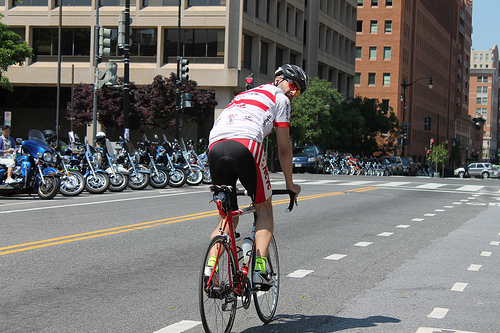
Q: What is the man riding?
A: A bicycle.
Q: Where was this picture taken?
A: On a road.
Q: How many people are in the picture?
A: 1.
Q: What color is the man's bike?
A: Red.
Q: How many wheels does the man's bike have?
A: 2.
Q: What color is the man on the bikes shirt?
A: Red and white.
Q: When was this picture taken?
A: Daytime.